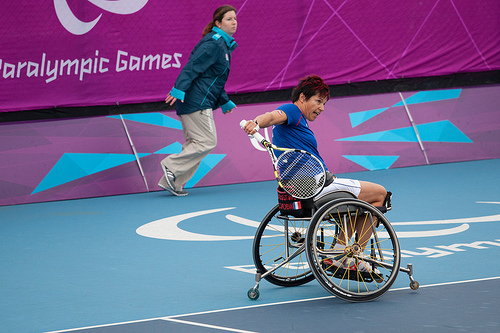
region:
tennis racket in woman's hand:
[240, 116, 328, 200]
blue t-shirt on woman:
[271, 101, 327, 178]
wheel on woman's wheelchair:
[305, 197, 401, 302]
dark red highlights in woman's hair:
[301, 75, 331, 93]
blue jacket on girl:
[168, 27, 235, 113]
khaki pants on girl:
[161, 108, 220, 188]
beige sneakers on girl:
[158, 162, 193, 199]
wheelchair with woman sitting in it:
[247, 177, 419, 303]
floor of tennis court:
[2, 156, 497, 331]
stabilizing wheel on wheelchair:
[247, 286, 261, 301]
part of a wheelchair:
[242, 175, 423, 312]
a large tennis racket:
[257, 125, 329, 200]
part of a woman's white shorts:
[308, 170, 358, 200]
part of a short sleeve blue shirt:
[270, 105, 327, 177]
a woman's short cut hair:
[287, 75, 332, 110]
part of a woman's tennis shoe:
[162, 161, 176, 188]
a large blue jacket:
[165, 33, 243, 113]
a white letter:
[402, 240, 449, 262]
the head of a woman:
[215, 8, 239, 34]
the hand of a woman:
[244, 120, 261, 131]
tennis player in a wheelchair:
[231, 70, 430, 314]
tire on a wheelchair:
[306, 186, 414, 312]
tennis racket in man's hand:
[251, 123, 328, 202]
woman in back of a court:
[146, 5, 258, 202]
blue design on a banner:
[336, 93, 459, 176]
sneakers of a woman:
[151, 153, 191, 201]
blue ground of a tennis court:
[140, 293, 442, 323]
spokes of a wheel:
[268, 218, 283, 264]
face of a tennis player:
[288, 70, 333, 122]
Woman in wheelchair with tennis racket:
[239, 74, 424, 301]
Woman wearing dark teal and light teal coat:
[155, 3, 238, 193]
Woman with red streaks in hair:
[239, 74, 391, 276]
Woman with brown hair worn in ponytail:
[156, 4, 238, 196]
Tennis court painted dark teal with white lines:
[42, 275, 499, 331]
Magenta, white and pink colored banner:
[0, 0, 499, 117]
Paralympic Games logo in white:
[0, 0, 185, 84]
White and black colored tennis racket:
[237, 118, 327, 200]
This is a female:
[228, 58, 420, 298]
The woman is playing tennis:
[225, 73, 434, 315]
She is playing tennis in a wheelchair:
[223, 65, 426, 311]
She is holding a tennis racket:
[236, 93, 340, 198]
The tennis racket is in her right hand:
[238, 110, 336, 212]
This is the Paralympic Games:
[4, 47, 182, 83]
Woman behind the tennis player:
[160, 6, 244, 197]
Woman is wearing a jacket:
[165, 9, 247, 120]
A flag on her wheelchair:
[280, 192, 308, 211]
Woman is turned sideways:
[240, 75, 429, 307]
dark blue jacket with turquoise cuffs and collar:
[162, 26, 233, 116]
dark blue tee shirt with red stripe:
[269, 103, 329, 187]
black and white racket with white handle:
[237, 120, 328, 200]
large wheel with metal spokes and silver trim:
[305, 195, 402, 302]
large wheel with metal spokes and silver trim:
[253, 198, 344, 288]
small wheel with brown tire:
[248, 285, 258, 301]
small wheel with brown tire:
[408, 279, 418, 289]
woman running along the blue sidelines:
[145, 6, 240, 195]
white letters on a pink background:
[0, 0, 499, 114]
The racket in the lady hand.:
[237, 105, 328, 202]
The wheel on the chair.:
[291, 200, 406, 297]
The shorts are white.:
[310, 175, 375, 195]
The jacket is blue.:
[182, 40, 232, 95]